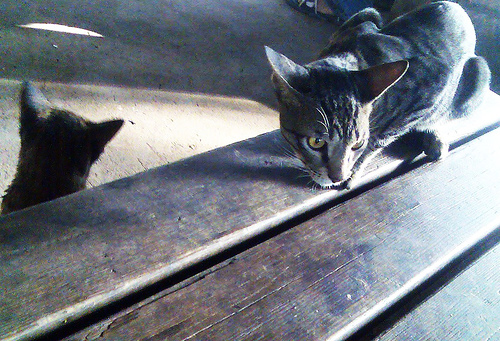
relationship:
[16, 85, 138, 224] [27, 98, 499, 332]
cat standing in ground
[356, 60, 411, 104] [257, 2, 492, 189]
ear on cat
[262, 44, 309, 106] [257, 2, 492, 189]
ear on cat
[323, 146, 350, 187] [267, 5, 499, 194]
nose on cat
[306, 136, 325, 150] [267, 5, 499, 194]
eye on cat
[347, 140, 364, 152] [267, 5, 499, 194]
eye on cat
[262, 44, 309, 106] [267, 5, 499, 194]
ear on cat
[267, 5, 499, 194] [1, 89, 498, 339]
cat on table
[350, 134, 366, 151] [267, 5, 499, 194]
eye on cat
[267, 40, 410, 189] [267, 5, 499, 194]
head on cat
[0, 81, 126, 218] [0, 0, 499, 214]
cat sitting on floor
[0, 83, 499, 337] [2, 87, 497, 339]
wood slates on table top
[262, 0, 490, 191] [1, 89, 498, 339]
cat crouched on table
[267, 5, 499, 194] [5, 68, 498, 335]
cat crouched on bench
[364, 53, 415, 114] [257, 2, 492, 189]
ear on cat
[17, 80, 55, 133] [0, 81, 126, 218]
ear of cat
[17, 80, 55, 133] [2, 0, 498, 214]
ear in floor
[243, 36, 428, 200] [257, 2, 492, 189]
head of cat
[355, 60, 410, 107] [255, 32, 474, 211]
ear of cat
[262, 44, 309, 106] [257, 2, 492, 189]
ear of cat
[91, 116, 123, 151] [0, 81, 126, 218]
ear of cat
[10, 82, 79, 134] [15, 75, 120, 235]
ear of cat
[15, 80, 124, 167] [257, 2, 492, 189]
head on cat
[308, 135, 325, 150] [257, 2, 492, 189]
eye on cat